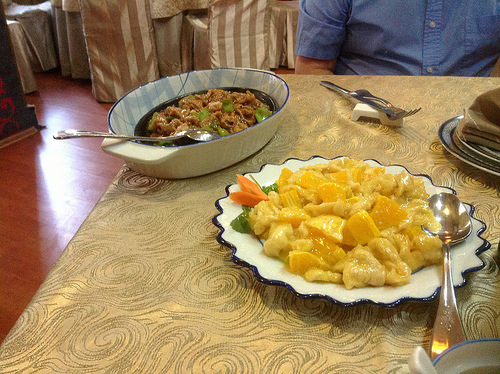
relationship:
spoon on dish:
[413, 174, 497, 254] [201, 210, 255, 265]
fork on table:
[342, 52, 434, 140] [275, 108, 325, 157]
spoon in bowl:
[413, 174, 497, 254] [78, 139, 243, 204]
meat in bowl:
[167, 79, 243, 138] [78, 139, 243, 204]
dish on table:
[201, 210, 255, 265] [275, 108, 325, 157]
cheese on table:
[284, 174, 377, 237] [275, 108, 325, 157]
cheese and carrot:
[284, 174, 377, 237] [218, 179, 264, 221]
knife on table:
[350, 79, 412, 120] [275, 108, 325, 157]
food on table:
[112, 41, 471, 323] [275, 108, 325, 157]